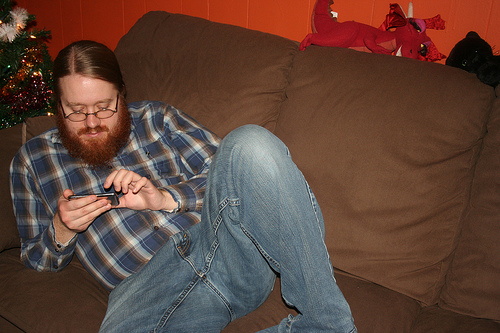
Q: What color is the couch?
A: Brown.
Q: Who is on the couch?
A: A man.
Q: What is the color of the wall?
A: Orange.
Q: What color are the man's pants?
A: Blue.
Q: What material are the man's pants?
A: Denim.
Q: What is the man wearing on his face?
A: Glasses.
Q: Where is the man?
A: On the couch.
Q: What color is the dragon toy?
A: Red.